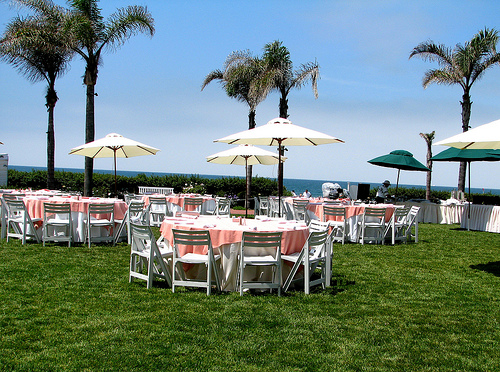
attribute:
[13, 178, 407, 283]
tables — round, white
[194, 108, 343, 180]
parsol — yellow, beige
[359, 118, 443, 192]
parasol — green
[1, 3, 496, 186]
sky — blue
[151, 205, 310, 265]
tablecloth — orange, pink, white, peach colored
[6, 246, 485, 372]
grass — green, cut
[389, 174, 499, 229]
tablecloth — white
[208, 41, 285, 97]
palm tree — green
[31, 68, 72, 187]
trunk — brown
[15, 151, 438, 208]
water — blue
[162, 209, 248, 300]
chair — white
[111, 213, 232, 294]
chairs — white, folding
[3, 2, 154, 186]
palm trees — slender, dry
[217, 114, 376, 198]
umbrellas — white, large, green